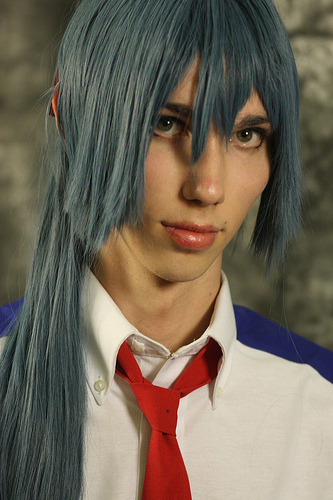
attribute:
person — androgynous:
[33, 1, 298, 373]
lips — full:
[159, 217, 222, 252]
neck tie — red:
[122, 336, 224, 498]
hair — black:
[0, 0, 304, 498]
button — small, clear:
[90, 377, 105, 394]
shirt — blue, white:
[0, 274, 331, 495]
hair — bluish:
[47, 61, 134, 176]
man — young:
[59, 32, 230, 235]